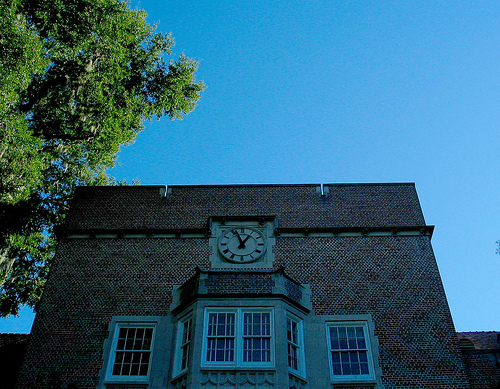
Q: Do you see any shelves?
A: No, there are no shelves.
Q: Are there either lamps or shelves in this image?
A: No, there are no shelves or lamps.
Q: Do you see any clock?
A: Yes, there is a clock.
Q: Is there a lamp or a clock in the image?
A: Yes, there is a clock.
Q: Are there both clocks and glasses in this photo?
A: No, there is a clock but no glasses.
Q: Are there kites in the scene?
A: No, there are no kites.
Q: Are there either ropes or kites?
A: No, there are no kites or ropes.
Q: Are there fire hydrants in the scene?
A: No, there are no fire hydrants.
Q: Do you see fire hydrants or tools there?
A: No, there are no fire hydrants or tools.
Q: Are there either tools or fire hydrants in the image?
A: No, there are no fire hydrants or tools.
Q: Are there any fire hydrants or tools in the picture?
A: No, there are no fire hydrants or tools.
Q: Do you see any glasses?
A: No, there are no glasses.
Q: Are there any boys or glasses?
A: No, there are no glasses or boys.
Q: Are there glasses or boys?
A: No, there are no glasses or boys.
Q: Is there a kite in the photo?
A: No, there are no kites.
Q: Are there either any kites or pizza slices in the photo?
A: No, there are no kites or pizza slices.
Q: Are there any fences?
A: No, there are no fences.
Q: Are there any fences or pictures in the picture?
A: No, there are no fences or pictures.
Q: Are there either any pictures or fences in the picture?
A: No, there are no fences or pictures.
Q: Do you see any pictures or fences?
A: No, there are no fences or pictures.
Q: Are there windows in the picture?
A: Yes, there is a window.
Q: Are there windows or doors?
A: Yes, there is a window.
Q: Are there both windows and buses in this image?
A: No, there is a window but no buses.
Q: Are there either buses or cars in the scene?
A: No, there are no cars or buses.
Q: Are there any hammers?
A: No, there are no hammers.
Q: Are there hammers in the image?
A: No, there are no hammers.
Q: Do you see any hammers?
A: No, there are no hammers.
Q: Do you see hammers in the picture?
A: No, there are no hammers.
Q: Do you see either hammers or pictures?
A: No, there are no hammers or pictures.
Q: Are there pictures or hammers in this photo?
A: No, there are no hammers or pictures.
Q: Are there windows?
A: Yes, there is a window.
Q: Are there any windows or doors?
A: Yes, there is a window.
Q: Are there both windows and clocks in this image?
A: Yes, there are both a window and a clock.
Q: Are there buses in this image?
A: No, there are no buses.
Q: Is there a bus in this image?
A: No, there are no buses.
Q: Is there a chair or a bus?
A: No, there are no buses or chairs.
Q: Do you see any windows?
A: Yes, there is a window.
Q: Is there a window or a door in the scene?
A: Yes, there is a window.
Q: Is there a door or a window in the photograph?
A: Yes, there is a window.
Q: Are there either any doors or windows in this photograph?
A: Yes, there is a window.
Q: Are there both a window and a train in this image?
A: No, there is a window but no trains.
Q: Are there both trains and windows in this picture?
A: No, there is a window but no trains.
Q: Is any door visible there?
A: No, there are no doors.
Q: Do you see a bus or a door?
A: No, there are no doors or buses.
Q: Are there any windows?
A: Yes, there is a window.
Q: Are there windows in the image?
A: Yes, there is a window.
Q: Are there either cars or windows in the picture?
A: Yes, there is a window.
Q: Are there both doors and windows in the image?
A: No, there is a window but no doors.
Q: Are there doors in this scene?
A: No, there are no doors.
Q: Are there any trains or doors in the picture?
A: No, there are no doors or trains.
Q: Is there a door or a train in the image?
A: No, there are no doors or trains.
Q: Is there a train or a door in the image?
A: No, there are no doors or trains.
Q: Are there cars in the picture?
A: No, there are no cars.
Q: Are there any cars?
A: No, there are no cars.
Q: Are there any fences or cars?
A: No, there are no cars or fences.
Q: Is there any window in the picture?
A: Yes, there are windows.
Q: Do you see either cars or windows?
A: Yes, there are windows.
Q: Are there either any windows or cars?
A: Yes, there are windows.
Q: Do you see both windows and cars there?
A: No, there are windows but no cars.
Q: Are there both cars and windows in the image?
A: No, there are windows but no cars.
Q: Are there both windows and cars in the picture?
A: No, there are windows but no cars.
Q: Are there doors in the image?
A: No, there are no doors.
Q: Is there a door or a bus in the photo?
A: No, there are no doors or buses.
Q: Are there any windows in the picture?
A: Yes, there are windows.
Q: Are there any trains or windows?
A: Yes, there are windows.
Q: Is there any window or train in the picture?
A: Yes, there are windows.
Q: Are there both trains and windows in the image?
A: No, there are windows but no trains.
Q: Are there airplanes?
A: No, there are no airplanes.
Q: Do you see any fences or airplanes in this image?
A: No, there are no airplanes or fences.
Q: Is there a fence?
A: No, there are no fences.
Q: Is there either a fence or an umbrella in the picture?
A: No, there are no fences or umbrellas.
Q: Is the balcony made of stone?
A: Yes, the balcony is made of stone.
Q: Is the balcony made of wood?
A: No, the balcony is made of stone.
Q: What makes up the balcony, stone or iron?
A: The balcony is made of stone.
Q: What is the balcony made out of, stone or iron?
A: The balcony is made of stone.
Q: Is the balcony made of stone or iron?
A: The balcony is made of stone.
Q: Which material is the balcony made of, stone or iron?
A: The balcony is made of stone.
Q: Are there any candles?
A: No, there are no candles.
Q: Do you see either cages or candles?
A: No, there are no candles or cages.